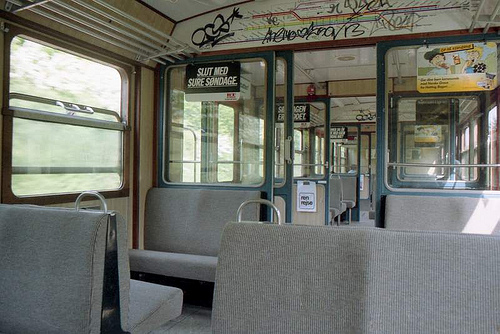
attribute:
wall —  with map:
[183, 0, 498, 47]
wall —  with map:
[174, 0, 484, 50]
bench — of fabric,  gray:
[128, 184, 261, 279]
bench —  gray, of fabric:
[4, 204, 106, 331]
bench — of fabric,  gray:
[212, 222, 498, 331]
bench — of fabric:
[386, 194, 497, 232]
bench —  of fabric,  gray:
[108, 211, 184, 330]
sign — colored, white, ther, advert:
[184, 63, 240, 98]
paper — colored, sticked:
[184, 57, 247, 109]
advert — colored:
[413, 36, 498, 99]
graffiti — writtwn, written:
[188, 13, 250, 44]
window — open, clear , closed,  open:
[12, 96, 126, 196]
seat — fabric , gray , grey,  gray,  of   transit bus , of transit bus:
[203, 196, 499, 334]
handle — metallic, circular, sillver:
[230, 194, 287, 224]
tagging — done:
[368, 21, 410, 42]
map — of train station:
[312, 34, 348, 94]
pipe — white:
[378, 165, 415, 169]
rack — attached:
[36, 3, 212, 70]